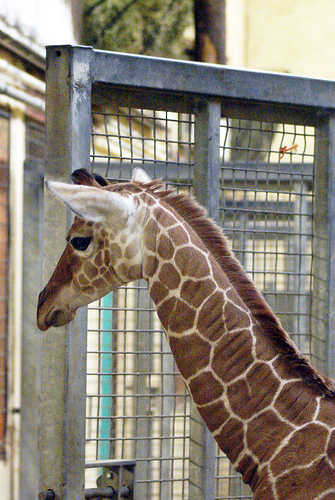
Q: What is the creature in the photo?
A: Giraffe.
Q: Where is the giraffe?
A: In a pen.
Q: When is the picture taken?
A: Daytime.